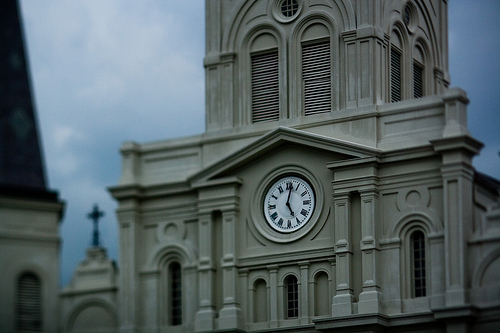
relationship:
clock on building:
[257, 172, 320, 235] [34, 7, 499, 331]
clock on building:
[257, 172, 319, 232] [102, 0, 499, 330]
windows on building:
[166, 260, 183, 328] [102, 0, 499, 330]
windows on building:
[284, 275, 299, 318] [102, 0, 499, 330]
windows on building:
[410, 231, 427, 299] [102, 0, 499, 330]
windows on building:
[279, 1, 298, 16] [102, 0, 499, 330]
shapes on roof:
[5, 38, 46, 153] [0, 182, 69, 213]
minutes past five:
[284, 179, 300, 209] [283, 201, 305, 228]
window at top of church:
[240, 10, 340, 125] [104, 0, 499, 329]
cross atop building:
[80, 202, 110, 244] [55, 199, 118, 331]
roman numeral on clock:
[292, 178, 305, 193] [230, 159, 342, 264]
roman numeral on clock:
[284, 215, 292, 229] [230, 159, 342, 264]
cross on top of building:
[80, 202, 110, 244] [118, 12, 488, 331]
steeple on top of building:
[3, 2, 59, 219] [3, 210, 75, 330]